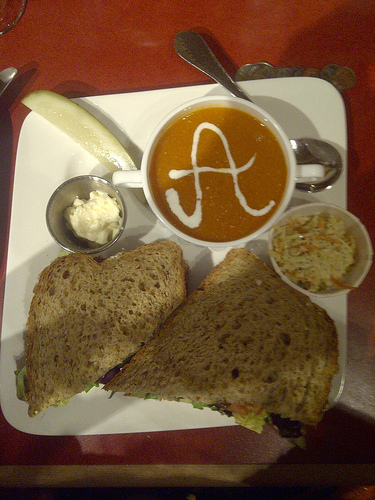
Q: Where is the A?
A: In the cup.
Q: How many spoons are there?
A: One.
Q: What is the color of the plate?
A: White.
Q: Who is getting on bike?
A: No one.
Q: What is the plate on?
A: Table.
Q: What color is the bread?
A: Brown.